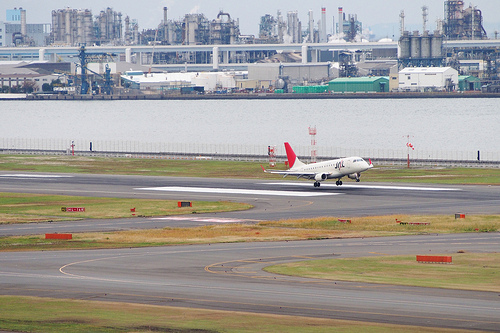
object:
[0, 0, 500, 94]
building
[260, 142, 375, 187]
airplane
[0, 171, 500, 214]
runway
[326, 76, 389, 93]
barn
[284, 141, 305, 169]
fin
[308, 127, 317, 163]
antenna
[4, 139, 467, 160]
river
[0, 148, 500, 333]
airport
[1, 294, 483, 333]
grass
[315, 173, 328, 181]
engine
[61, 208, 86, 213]
letters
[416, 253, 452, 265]
mmarker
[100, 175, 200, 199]
rectangle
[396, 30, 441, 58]
batteries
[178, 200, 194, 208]
marker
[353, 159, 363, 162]
windows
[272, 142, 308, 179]
tail fin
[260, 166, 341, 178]
wing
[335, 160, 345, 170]
logo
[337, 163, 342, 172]
door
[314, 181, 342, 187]
landing gear